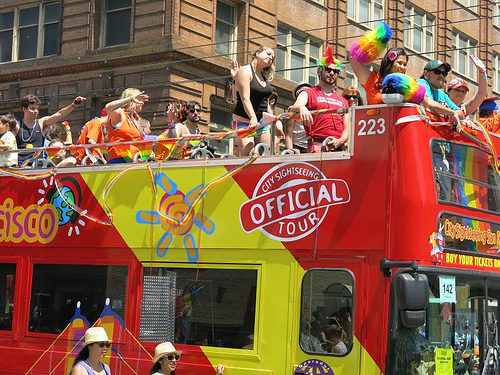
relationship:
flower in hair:
[388, 47, 401, 62] [376, 48, 406, 78]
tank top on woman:
[110, 111, 144, 157] [103, 82, 152, 160]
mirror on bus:
[380, 256, 431, 331] [0, 106, 495, 370]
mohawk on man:
[320, 46, 337, 69] [294, 54, 345, 151]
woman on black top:
[230, 42, 274, 156] [230, 64, 274, 120]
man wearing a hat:
[416, 54, 468, 111] [424, 56, 453, 76]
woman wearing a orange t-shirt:
[103, 87, 149, 162] [105, 110, 145, 160]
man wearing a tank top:
[294, 54, 345, 151] [236, 62, 271, 118]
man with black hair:
[16, 92, 61, 179] [17, 90, 39, 105]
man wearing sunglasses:
[158, 100, 201, 159] [188, 107, 201, 112]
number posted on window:
[440, 278, 456, 300] [431, 283, 497, 365]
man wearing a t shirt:
[278, 46, 360, 141] [299, 82, 346, 132]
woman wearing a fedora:
[64, 321, 121, 373] [78, 321, 110, 347]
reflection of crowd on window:
[303, 305, 348, 354] [299, 264, 352, 354]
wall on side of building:
[9, 1, 183, 151] [0, 7, 172, 125]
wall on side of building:
[9, 1, 183, 151] [6, 6, 498, 136]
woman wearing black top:
[230, 42, 274, 156] [230, 64, 274, 120]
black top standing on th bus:
[230, 64, 274, 120] [0, 106, 495, 370]